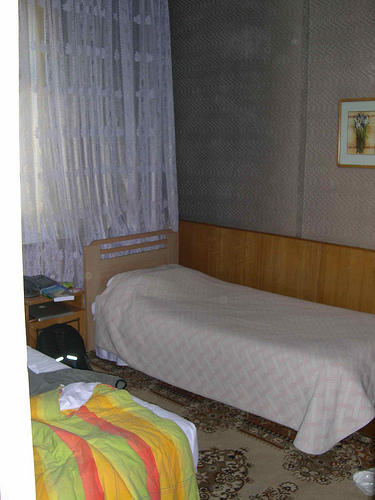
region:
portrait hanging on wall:
[327, 92, 373, 178]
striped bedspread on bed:
[40, 397, 189, 495]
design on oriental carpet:
[203, 438, 250, 495]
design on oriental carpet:
[286, 444, 340, 481]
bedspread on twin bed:
[171, 300, 312, 378]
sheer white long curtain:
[44, 74, 168, 220]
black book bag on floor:
[31, 323, 104, 369]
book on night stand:
[44, 285, 74, 304]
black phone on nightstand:
[24, 272, 52, 289]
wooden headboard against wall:
[74, 228, 178, 265]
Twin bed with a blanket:
[79, 224, 371, 490]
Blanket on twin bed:
[77, 225, 374, 450]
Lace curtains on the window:
[42, 125, 187, 282]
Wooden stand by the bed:
[27, 267, 91, 361]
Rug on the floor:
[91, 358, 374, 496]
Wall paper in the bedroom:
[180, 115, 374, 269]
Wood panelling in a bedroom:
[170, 203, 374, 327]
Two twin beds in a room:
[22, 224, 352, 498]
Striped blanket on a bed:
[27, 370, 203, 499]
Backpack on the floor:
[35, 319, 105, 387]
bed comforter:
[156, 277, 289, 380]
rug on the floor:
[203, 427, 282, 485]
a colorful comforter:
[52, 418, 174, 475]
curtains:
[42, 141, 158, 220]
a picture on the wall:
[332, 121, 373, 169]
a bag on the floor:
[37, 331, 92, 362]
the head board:
[84, 242, 177, 265]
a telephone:
[24, 272, 52, 288]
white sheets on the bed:
[35, 352, 57, 370]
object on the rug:
[344, 469, 374, 494]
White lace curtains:
[31, 2, 158, 213]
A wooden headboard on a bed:
[76, 227, 199, 292]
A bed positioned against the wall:
[90, 218, 366, 411]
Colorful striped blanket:
[35, 361, 192, 488]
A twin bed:
[84, 249, 369, 419]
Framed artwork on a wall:
[330, 90, 370, 184]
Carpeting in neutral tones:
[202, 421, 324, 494]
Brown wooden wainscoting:
[180, 207, 368, 307]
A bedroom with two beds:
[34, 184, 364, 496]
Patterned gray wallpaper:
[188, 122, 335, 222]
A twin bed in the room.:
[100, 238, 374, 415]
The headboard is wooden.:
[89, 229, 204, 276]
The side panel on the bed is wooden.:
[179, 216, 340, 299]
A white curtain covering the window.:
[51, 10, 160, 203]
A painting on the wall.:
[328, 67, 371, 176]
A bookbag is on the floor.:
[45, 329, 94, 377]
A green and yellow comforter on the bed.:
[45, 425, 173, 482]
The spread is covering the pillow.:
[116, 272, 331, 388]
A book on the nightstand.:
[41, 272, 79, 307]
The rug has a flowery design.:
[210, 403, 293, 482]